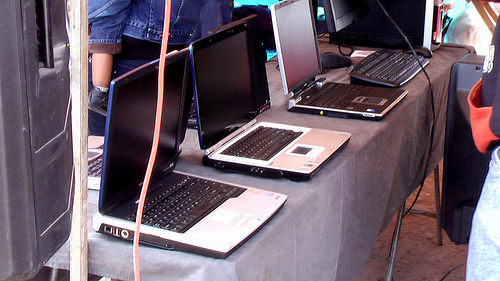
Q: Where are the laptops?
A: There are no laptops.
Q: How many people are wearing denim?
A: None.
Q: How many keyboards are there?
A: 4.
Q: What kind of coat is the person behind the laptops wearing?
A: Denim jacket.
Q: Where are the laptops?
A: On the table.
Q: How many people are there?
A: 2.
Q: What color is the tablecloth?
A: Gray.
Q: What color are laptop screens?
A: Black.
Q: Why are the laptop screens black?
A: Not on.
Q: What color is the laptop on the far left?
A: Silver.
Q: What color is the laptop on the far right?
A: Black.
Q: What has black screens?
A: Three laptops.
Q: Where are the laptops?
A: On the table.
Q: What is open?
A: The laptops.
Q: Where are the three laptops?
A: On the table.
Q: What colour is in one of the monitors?
A: Black.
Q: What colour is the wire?
A: Orange.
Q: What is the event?
A: A sale.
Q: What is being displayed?
A: Laptops.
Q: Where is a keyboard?
A: Lined up with the laptops.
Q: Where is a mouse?
A: Next to the keyboard.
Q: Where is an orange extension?
A: Hanging from the left.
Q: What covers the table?
A: A gray cloth.